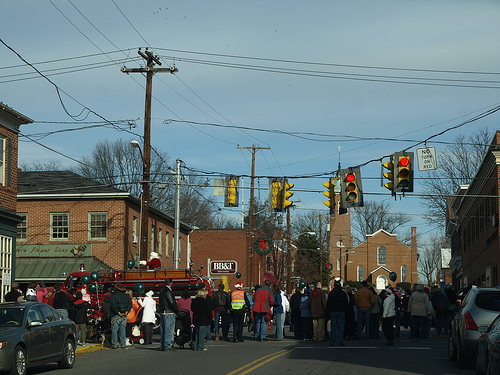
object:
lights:
[224, 174, 240, 207]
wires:
[183, 85, 229, 123]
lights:
[280, 176, 296, 212]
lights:
[322, 177, 336, 215]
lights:
[340, 165, 365, 208]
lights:
[392, 151, 415, 192]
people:
[324, 280, 350, 347]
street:
[0, 281, 500, 375]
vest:
[230, 290, 246, 311]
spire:
[336, 144, 342, 177]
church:
[325, 143, 421, 286]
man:
[108, 281, 133, 350]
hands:
[117, 311, 124, 316]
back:
[110, 291, 133, 313]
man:
[227, 281, 251, 343]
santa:
[138, 250, 162, 269]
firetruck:
[59, 267, 217, 336]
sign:
[208, 260, 238, 276]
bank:
[209, 260, 238, 275]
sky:
[0, 0, 500, 285]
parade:
[0, 269, 457, 352]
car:
[0, 299, 79, 375]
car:
[447, 283, 500, 371]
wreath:
[253, 235, 274, 257]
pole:
[249, 142, 257, 287]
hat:
[233, 281, 243, 289]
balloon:
[389, 271, 398, 281]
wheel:
[9, 344, 30, 375]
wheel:
[61, 337, 77, 368]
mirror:
[25, 319, 43, 328]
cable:
[357, 108, 500, 168]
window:
[87, 211, 108, 242]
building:
[14, 168, 194, 294]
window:
[49, 212, 71, 242]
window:
[14, 212, 29, 244]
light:
[465, 310, 480, 331]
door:
[374, 274, 388, 293]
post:
[206, 257, 212, 284]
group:
[223, 151, 416, 216]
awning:
[15, 254, 111, 284]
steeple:
[326, 143, 355, 287]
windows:
[376, 245, 386, 266]